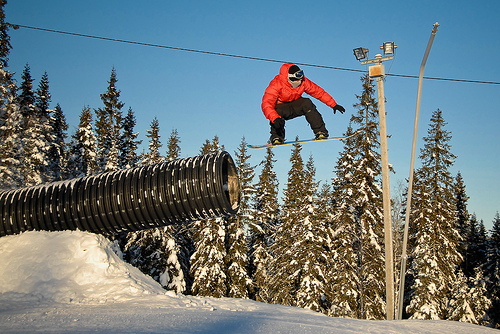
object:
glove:
[332, 104, 345, 114]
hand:
[333, 104, 345, 115]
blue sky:
[0, 0, 499, 236]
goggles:
[286, 69, 309, 81]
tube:
[0, 150, 242, 237]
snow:
[0, 152, 240, 236]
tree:
[294, 150, 325, 313]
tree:
[307, 73, 396, 321]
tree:
[0, 0, 35, 190]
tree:
[63, 104, 99, 179]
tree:
[122, 115, 187, 295]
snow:
[405, 144, 479, 324]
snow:
[316, 85, 395, 321]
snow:
[123, 116, 187, 294]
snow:
[63, 117, 98, 172]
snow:
[18, 94, 60, 179]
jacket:
[261, 62, 337, 123]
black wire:
[0, 23, 500, 85]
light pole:
[373, 57, 393, 320]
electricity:
[5, 23, 500, 84]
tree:
[396, 107, 464, 325]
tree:
[260, 134, 306, 306]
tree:
[293, 178, 335, 315]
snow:
[298, 215, 314, 231]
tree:
[91, 65, 126, 172]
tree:
[15, 61, 51, 188]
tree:
[321, 73, 385, 321]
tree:
[163, 126, 181, 161]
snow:
[0, 227, 500, 334]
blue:
[162, 58, 225, 114]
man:
[260, 62, 345, 145]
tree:
[176, 133, 229, 297]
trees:
[485, 210, 500, 320]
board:
[246, 130, 364, 150]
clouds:
[3, 1, 498, 235]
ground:
[0, 228, 500, 334]